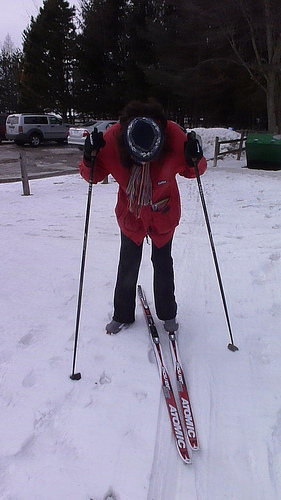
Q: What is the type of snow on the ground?
A: Powdery.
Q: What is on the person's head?
A: A hat.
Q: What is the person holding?
A: Ski poles.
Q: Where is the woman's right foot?
A: On the ski.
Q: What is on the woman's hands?
A: Gloves.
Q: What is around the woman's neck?
A: A scarf.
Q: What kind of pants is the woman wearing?
A: Long black pants.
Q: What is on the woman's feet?
A: Boots.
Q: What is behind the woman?
A: Cars.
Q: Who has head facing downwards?
A: Skier holding ski poles.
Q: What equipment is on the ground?
A: A pair of skis.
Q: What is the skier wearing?
A: A red winter coat.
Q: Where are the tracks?
A: In the snow.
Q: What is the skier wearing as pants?
A: A pair of long dark pants.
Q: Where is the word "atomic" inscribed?
A: On the red skis.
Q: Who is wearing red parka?
A: A woman.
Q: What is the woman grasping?
A: Ski poles.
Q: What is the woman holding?
A: Poles.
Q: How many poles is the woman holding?
A: Two.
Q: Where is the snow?
A: On the ground.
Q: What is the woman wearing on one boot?
A: Ski.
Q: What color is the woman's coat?
A: Red.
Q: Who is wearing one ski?
A: The woman.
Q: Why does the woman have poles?
A: To ski.